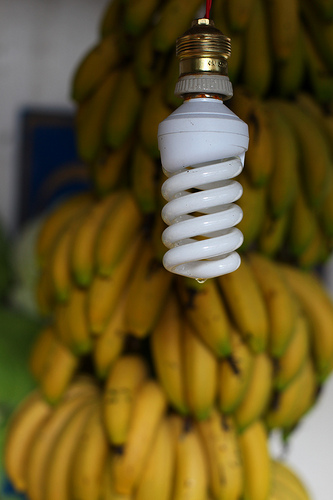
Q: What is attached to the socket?
A: Light bulb.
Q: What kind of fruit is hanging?
A: Bananas.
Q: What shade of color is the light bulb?
A: White.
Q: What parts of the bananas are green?
A: The tips.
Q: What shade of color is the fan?
A: There is no fan in the picture.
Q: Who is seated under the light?
A: There are no people in the photo.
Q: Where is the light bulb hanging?
A: In front of bananas.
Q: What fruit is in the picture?
A: Bananas.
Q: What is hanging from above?
A: A white light bulb.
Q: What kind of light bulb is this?
A: Energy saver.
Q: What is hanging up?
A: Lots of bananas.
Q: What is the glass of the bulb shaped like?
A: A corkscrew.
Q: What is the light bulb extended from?
A: A wire.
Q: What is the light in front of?
A: Bunches of bananas.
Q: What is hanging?
A: A white light.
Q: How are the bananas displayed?
A: In bunches.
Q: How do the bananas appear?
A: Ripe.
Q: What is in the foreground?
A: Lightbulb.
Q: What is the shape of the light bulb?
A: Spiral.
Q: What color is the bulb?
A: White.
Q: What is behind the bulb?
A: Bananas.